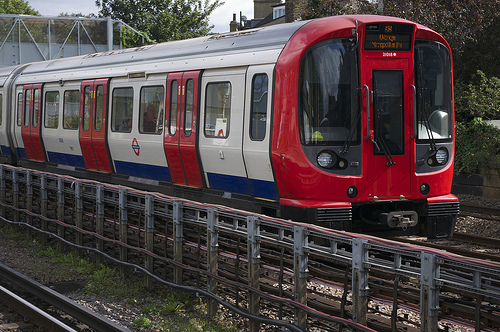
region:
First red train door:
[158, 67, 209, 204]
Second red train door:
[76, 74, 121, 185]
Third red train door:
[15, 75, 52, 176]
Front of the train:
[281, 14, 471, 219]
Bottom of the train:
[2, 157, 274, 325]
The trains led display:
[356, 15, 420, 57]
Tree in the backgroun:
[92, 7, 210, 34]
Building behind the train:
[229, 4, 296, 19]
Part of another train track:
[1, 259, 75, 330]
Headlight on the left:
[316, 145, 351, 180]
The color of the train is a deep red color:
[313, 24, 454, 219]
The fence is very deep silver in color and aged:
[331, 236, 375, 320]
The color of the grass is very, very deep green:
[106, 285, 148, 325]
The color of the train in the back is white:
[225, 70, 277, 192]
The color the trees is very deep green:
[469, 122, 489, 186]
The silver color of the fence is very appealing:
[82, 18, 114, 58]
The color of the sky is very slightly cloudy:
[219, 12, 225, 20]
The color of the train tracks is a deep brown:
[473, 235, 493, 267]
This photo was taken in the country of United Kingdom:
[91, 25, 434, 330]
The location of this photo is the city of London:
[121, 30, 416, 319]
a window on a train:
[251, 74, 267, 140]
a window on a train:
[204, 82, 230, 136]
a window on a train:
[184, 78, 192, 137]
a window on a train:
[164, 78, 176, 132]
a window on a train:
[138, 85, 164, 130]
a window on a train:
[111, 87, 136, 129]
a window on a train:
[91, 85, 103, 126]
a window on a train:
[81, 83, 91, 128]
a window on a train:
[61, 90, 83, 131]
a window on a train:
[44, 88, 61, 130]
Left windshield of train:
[410, 35, 455, 175]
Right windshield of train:
[293, 30, 363, 175]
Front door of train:
[360, 52, 413, 198]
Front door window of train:
[370, 60, 405, 160]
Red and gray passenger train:
[10, 11, 460, 236]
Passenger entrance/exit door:
[165, 71, 202, 183]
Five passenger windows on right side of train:
[40, 86, 232, 136]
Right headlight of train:
[310, 143, 342, 168]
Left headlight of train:
[426, 145, 451, 166]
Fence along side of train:
[10, 157, 440, 325]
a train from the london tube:
[7, 10, 462, 301]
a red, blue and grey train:
[3, 24, 388, 216]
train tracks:
[395, 232, 477, 304]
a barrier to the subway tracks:
[37, 173, 282, 329]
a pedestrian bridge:
[17, 6, 112, 44]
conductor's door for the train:
[356, 41, 419, 198]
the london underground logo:
[125, 122, 150, 162]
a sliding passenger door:
[165, 69, 201, 191]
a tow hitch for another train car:
[380, 205, 455, 232]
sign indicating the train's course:
[127, 69, 154, 79]